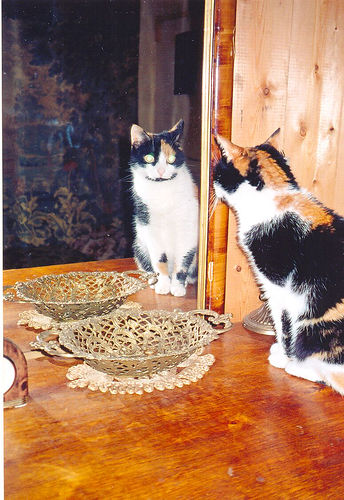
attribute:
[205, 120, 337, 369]
cat — looking, scratching, calico, sitting, scary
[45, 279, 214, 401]
basket — golden, wicker, reflecting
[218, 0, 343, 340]
wall — wood, wood panel, wooden, paneled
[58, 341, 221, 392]
coaster — knitted, fancy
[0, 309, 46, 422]
clock — wooden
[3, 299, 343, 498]
dresser — wooden, scratched, brown, antique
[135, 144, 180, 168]
eyes — green, reflecting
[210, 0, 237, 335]
frame — wooden, antique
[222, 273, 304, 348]
lamp — silver, behind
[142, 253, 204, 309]
front paws — white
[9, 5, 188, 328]
mirror — framed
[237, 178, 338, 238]
neck — orange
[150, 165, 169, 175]
nose — pink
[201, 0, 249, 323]
trim — wood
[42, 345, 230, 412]
doiley — crocheted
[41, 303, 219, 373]
bowl — silver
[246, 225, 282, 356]
candle stick — hidden